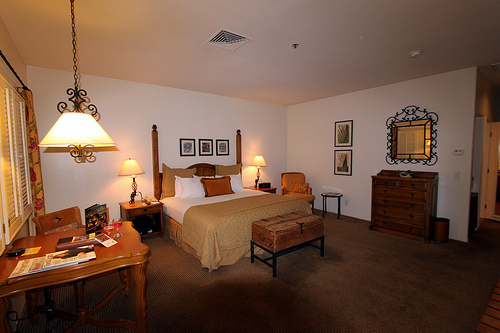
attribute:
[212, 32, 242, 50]
vent — white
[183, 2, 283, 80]
ceiling — white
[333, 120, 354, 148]
picture — framed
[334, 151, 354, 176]
picture — framed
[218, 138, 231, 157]
picture — framed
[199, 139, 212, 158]
picture — framed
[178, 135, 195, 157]
picture — framed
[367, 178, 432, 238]
dresser — wood, brown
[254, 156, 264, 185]
lamp — on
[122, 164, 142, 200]
lamp — on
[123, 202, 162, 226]
stand — wood, brown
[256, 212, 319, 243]
chest — wood, old